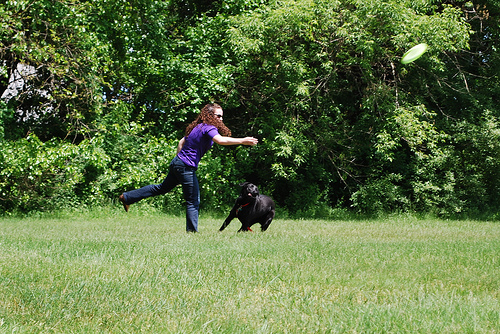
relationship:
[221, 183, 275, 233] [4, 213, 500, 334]
dog in a field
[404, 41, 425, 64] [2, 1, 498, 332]
frisbee in air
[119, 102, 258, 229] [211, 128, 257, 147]
lady has an arm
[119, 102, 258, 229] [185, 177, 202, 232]
lady has a foot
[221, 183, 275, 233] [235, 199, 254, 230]
dog has a leash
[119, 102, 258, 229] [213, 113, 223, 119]
lady wearing sunglasses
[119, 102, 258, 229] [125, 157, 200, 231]
lady wearing jeans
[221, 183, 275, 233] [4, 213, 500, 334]
dog in field